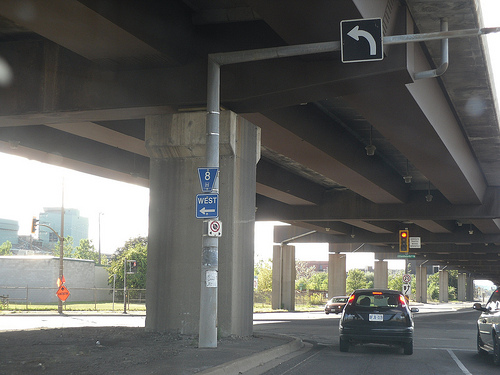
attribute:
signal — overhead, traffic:
[390, 216, 416, 257]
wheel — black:
[336, 334, 352, 351]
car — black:
[336, 279, 422, 354]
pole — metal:
[197, 52, 217, 347]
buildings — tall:
[12, 190, 139, 287]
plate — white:
[362, 310, 394, 328]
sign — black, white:
[338, 15, 384, 62]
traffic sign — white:
[207, 220, 223, 239]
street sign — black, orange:
[57, 285, 71, 308]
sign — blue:
[197, 160, 225, 198]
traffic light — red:
[394, 227, 411, 252]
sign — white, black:
[176, 148, 246, 244]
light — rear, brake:
[398, 291, 407, 307]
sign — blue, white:
[194, 167, 218, 223]